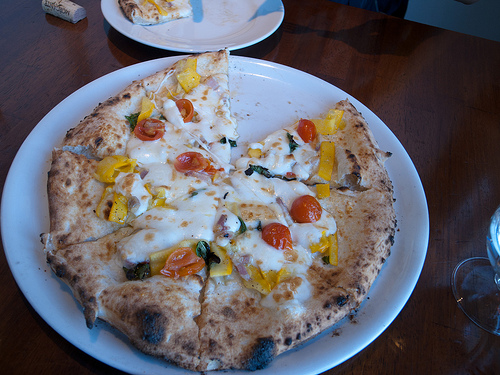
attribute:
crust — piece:
[69, 272, 351, 368]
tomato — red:
[292, 197, 317, 224]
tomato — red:
[264, 223, 291, 246]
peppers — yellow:
[80, 148, 143, 183]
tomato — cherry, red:
[173, 93, 195, 125]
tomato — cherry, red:
[134, 115, 165, 142]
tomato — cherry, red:
[171, 148, 208, 176]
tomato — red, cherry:
[161, 242, 204, 280]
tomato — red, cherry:
[260, 220, 295, 250]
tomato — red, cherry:
[288, 191, 322, 223]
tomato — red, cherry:
[296, 115, 316, 145]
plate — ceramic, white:
[8, 66, 495, 370]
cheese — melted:
[102, 151, 299, 251]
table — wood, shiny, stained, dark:
[4, 2, 497, 373]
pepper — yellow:
[302, 134, 347, 208]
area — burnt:
[236, 339, 278, 366]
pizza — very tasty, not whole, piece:
[38, 47, 400, 374]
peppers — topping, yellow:
[313, 106, 348, 186]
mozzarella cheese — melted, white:
[145, 212, 200, 252]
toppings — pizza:
[236, 190, 337, 265]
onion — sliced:
[276, 191, 295, 228]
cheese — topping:
[162, 200, 212, 240]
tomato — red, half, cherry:
[132, 113, 169, 142]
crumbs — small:
[241, 86, 304, 123]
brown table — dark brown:
[7, 9, 498, 369]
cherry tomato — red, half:
[296, 118, 321, 145]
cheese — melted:
[169, 188, 223, 247]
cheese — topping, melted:
[120, 110, 217, 170]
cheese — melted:
[236, 119, 314, 179]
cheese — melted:
[90, 71, 354, 300]